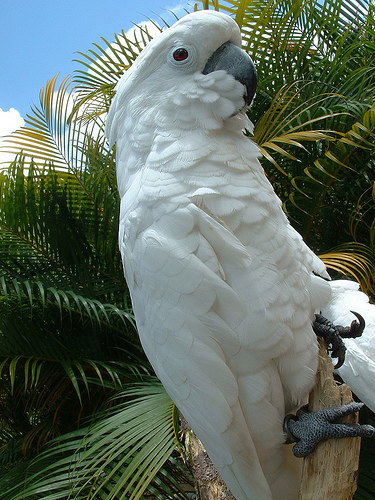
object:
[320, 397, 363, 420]
fingers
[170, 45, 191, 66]
eye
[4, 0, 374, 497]
trees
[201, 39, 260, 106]
beak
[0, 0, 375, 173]
sky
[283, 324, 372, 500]
stick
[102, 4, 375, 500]
parrot